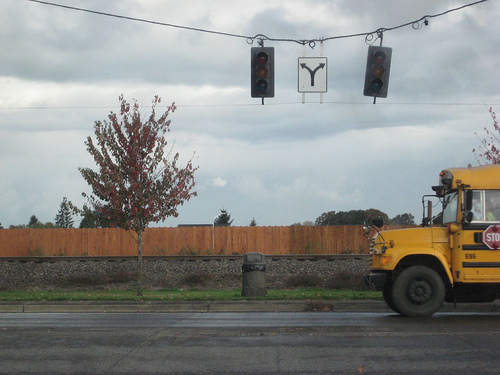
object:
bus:
[365, 162, 499, 321]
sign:
[479, 217, 499, 254]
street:
[0, 313, 499, 373]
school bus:
[359, 160, 499, 322]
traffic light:
[363, 45, 392, 99]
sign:
[297, 57, 329, 92]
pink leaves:
[147, 122, 154, 133]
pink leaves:
[163, 164, 172, 177]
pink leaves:
[185, 158, 192, 174]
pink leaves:
[94, 120, 102, 139]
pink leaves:
[142, 210, 154, 220]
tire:
[382, 264, 444, 314]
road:
[5, 300, 429, 365]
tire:
[383, 256, 458, 316]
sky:
[191, 95, 344, 182]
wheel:
[388, 259, 443, 320]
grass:
[2, 286, 391, 310]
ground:
[388, 161, 425, 180]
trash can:
[242, 252, 267, 297]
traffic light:
[358, 40, 395, 105]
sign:
[290, 39, 344, 100]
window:
[469, 191, 499, 223]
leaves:
[122, 130, 135, 146]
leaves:
[138, 182, 169, 193]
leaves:
[101, 161, 114, 178]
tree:
[77, 91, 204, 296]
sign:
[298, 52, 331, 96]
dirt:
[115, 325, 375, 337]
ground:
[4, 284, 441, 317]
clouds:
[14, 79, 483, 151]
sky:
[3, 1, 484, 221]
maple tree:
[64, 91, 202, 301]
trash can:
[238, 249, 269, 296]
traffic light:
[247, 34, 276, 105]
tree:
[61, 92, 201, 296]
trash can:
[237, 250, 269, 301]